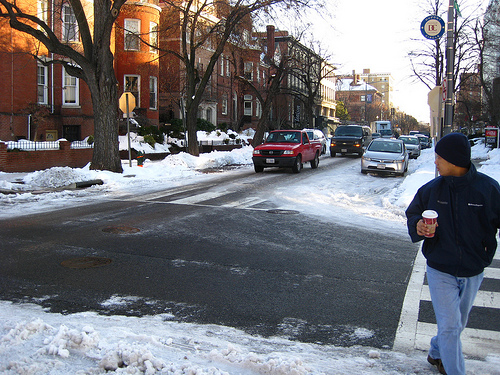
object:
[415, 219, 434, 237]
hand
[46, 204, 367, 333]
street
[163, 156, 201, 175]
snow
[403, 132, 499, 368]
man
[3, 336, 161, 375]
snow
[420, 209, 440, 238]
coffee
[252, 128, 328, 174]
truck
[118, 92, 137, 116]
back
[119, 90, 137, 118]
sign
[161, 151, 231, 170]
piles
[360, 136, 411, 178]
car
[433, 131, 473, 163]
cap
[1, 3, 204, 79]
sunlight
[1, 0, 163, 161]
buildings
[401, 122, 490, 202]
back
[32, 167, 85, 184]
snow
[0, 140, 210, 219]
sidewalks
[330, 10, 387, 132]
homes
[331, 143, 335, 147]
lights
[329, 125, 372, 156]
van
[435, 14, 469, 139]
pole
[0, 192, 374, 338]
road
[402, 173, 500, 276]
jacket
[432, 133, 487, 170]
hat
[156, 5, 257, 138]
buildings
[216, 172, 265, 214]
markings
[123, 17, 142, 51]
windows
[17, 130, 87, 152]
fence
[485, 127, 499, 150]
sign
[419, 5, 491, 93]
trees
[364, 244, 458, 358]
crosswalk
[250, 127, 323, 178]
cars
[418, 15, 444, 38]
sign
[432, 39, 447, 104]
pole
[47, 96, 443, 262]
intersection